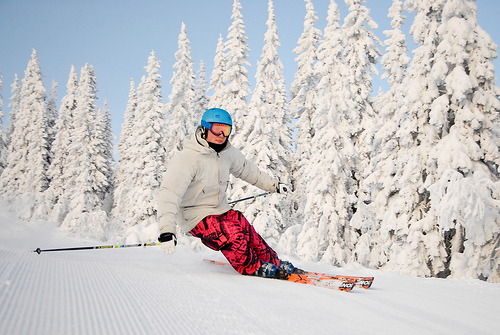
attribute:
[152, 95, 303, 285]
man — skiing slanted, skiing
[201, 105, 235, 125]
helmet — part, ski safety, blue fitted, blue, safety helmet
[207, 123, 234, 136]
goggles — reflective, blue, shiny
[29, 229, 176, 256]
ski pole — black, slanted, yellow, white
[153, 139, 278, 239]
jacket — beige, large, white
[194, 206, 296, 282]
pants — black, pink, black abstract, red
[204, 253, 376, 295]
skis — orange, white, black, downhill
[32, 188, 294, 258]
ski poles — white, black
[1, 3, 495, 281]
trees — forest, snow covered, pine trees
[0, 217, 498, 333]
snow — part, grate designed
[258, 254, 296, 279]
boots — ski boots, blue, orange, black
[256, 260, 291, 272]
buckles — silver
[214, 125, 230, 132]
lenses — amber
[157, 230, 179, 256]
gloves — black, white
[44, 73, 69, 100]
cloud — part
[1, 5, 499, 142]
sky — open, blue, clear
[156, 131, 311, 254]
coat — part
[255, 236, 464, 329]
board — part